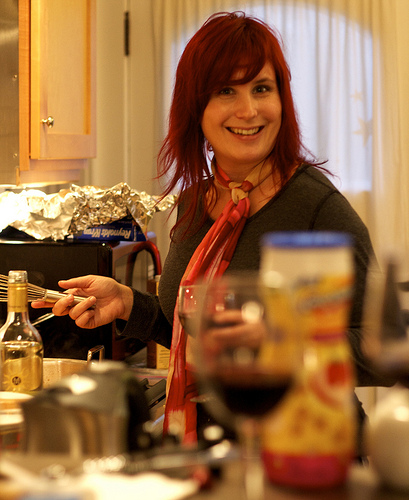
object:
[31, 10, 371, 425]
woman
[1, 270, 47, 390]
whisk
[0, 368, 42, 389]
oil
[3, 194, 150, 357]
oven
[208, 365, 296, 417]
wine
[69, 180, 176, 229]
wrap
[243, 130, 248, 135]
teeth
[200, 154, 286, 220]
scarf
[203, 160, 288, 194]
neck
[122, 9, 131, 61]
hinge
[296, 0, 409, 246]
curtain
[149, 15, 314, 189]
head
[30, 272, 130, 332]
hand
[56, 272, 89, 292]
thumb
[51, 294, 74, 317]
finger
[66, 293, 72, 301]
nail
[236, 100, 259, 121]
nose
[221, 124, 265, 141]
mouth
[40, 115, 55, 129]
handle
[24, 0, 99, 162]
cabinet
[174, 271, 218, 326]
glass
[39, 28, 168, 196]
wall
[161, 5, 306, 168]
hair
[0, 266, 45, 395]
bottle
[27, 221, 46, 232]
foil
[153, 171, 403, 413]
top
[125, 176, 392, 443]
shirt